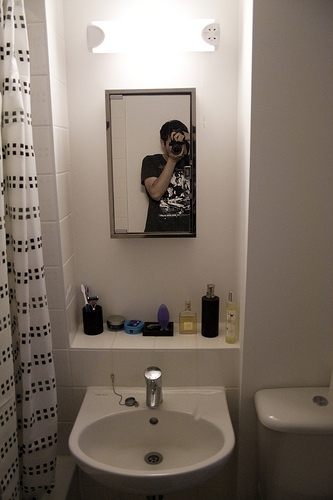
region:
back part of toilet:
[252, 386, 332, 497]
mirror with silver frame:
[103, 88, 196, 237]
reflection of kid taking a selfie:
[140, 119, 192, 232]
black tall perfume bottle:
[201, 282, 218, 337]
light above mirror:
[87, 18, 219, 51]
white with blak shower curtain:
[2, 1, 65, 496]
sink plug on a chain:
[109, 371, 138, 406]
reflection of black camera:
[169, 138, 189, 154]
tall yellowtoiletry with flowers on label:
[225, 290, 238, 345]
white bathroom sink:
[70, 382, 236, 493]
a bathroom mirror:
[106, 85, 198, 238]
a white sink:
[67, 379, 238, 491]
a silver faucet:
[143, 365, 168, 409]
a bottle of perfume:
[176, 296, 199, 335]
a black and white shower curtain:
[0, 0, 58, 499]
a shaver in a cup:
[87, 294, 99, 310]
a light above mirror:
[84, 14, 221, 54]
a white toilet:
[253, 384, 331, 499]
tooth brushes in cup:
[80, 283, 91, 311]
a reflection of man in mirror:
[140, 112, 191, 235]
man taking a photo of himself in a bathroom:
[15, 56, 316, 441]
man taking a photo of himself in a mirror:
[105, 89, 198, 236]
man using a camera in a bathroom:
[105, 88, 206, 431]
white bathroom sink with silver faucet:
[86, 361, 226, 482]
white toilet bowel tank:
[244, 365, 330, 498]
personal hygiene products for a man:
[75, 272, 239, 344]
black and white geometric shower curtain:
[0, 184, 60, 497]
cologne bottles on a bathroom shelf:
[179, 278, 238, 345]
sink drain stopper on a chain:
[102, 362, 143, 419]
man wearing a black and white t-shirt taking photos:
[140, 114, 193, 231]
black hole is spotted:
[150, 418, 158, 430]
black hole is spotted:
[148, 412, 164, 444]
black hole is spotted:
[148, 413, 159, 429]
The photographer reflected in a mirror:
[140, 119, 193, 232]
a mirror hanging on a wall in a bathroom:
[102, 87, 198, 239]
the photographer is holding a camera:
[165, 132, 187, 157]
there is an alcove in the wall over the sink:
[46, 2, 241, 346]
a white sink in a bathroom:
[69, 384, 235, 484]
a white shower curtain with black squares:
[0, 1, 59, 499]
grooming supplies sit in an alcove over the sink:
[75, 284, 237, 343]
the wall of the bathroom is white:
[45, 1, 331, 499]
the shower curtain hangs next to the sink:
[0, 0, 234, 499]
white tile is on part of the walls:
[24, 0, 239, 455]